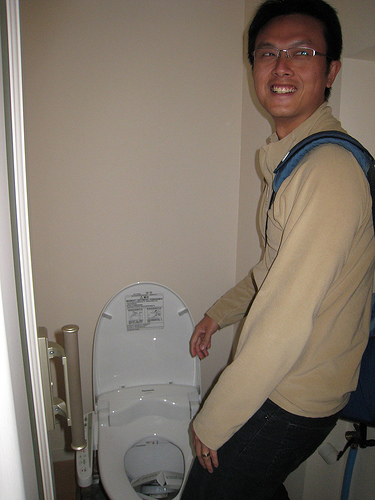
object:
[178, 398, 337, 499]
jeans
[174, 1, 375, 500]
man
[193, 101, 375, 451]
shirt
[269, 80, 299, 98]
smile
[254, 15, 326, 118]
face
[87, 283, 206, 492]
toilet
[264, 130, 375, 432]
backpack